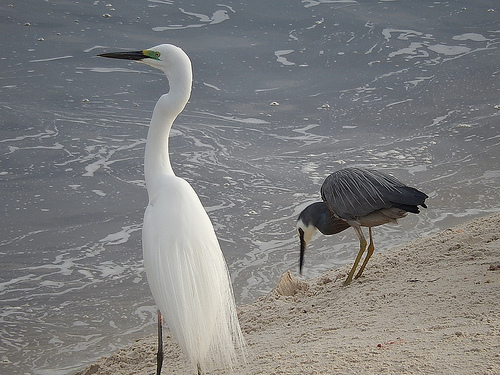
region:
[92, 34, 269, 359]
A white heron at the water's edge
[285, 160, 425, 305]
A black bird digging in the sand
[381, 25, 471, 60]
Bubbles floating on the water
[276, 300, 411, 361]
Wet sand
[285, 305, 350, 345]
Bird tracks in the sand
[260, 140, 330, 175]
The sun reflecting off the water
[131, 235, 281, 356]
Flowing white tail feathers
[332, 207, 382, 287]
Backwards bent knees on a bird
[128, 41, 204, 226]
A long white bird's neck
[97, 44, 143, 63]
A pointy black beak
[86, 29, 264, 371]
Tall white crane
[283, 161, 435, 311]
Black crane pecking in the sand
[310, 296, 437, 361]
Wet sandy beach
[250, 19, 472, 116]
Pond water with white foam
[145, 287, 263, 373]
Long white crane feathers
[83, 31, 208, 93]
Long black beak with some yellow and green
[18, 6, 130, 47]
Several small bubbles in the water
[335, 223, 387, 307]
Long skinny legs in the sand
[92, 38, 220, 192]
Very long powerful neck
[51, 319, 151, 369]
Wet sandy shoreline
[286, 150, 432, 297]
Bird pecking at the sand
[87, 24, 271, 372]
Large white bird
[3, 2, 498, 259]
White foam on the water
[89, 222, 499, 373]
Brown beach sand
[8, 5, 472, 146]
Grey murky water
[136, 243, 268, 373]
Bird wings have white hairlike feathers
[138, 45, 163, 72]
Green and yellow spot between eye and beak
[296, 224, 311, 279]
Black stripe goes straight from eye to beak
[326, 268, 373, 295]
Feet are under sand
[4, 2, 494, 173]
Water appears to be calm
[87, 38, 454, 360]
two different bird on shore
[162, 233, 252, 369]
wispy long white bird feathers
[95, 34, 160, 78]
long black beak of bird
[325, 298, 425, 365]
dry sandy beach shore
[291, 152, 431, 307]
black and white bird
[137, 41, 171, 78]
green and yellow birds eye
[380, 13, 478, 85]
white swirls in ocean water by shore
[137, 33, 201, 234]
long white neck of bird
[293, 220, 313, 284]
long black beak on small bird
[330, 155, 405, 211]
white lines on black bird feathers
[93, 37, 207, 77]
the head of the white bird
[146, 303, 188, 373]
the leg of the white bird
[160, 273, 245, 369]
the tail of the white bird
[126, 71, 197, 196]
the neck of the white bird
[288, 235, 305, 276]
the beak of the dark bird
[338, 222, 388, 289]
the legs of the dark bird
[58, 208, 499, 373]
a tan stretch of sand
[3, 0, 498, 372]
a gray body of water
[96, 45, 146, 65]
the beak of the white bird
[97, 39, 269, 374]
a large white bird